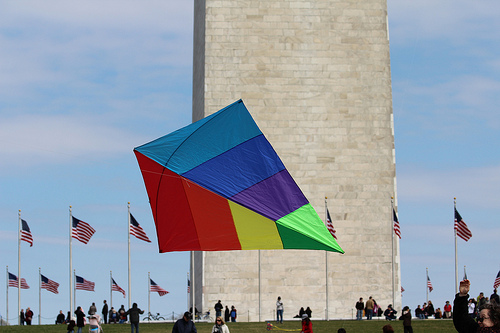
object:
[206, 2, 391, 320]
exterior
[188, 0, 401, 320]
monument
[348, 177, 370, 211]
wall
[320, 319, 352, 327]
grass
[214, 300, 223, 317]
person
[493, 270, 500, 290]
flag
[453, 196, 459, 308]
pole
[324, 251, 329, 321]
pole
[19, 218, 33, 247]
american flag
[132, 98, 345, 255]
flag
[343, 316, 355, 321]
grass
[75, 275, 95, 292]
american flags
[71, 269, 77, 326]
pole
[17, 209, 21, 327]
pole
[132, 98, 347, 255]
kite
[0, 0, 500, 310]
sky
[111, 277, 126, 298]
flag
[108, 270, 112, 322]
pole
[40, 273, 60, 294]
flag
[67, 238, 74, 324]
flagpole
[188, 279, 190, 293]
flag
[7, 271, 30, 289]
flag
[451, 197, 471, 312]
flag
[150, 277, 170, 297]
flag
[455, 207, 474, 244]
american flag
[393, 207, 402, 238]
american flag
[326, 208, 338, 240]
american flag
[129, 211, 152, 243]
american flag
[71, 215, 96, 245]
american flag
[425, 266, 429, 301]
pole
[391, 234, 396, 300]
pole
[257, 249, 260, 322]
pole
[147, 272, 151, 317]
pole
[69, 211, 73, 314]
pole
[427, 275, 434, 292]
flag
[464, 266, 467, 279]
pole